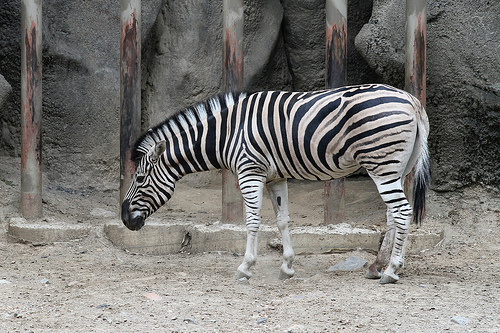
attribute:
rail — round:
[16, 0, 58, 227]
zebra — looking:
[119, 82, 430, 282]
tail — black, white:
[409, 96, 432, 230]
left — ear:
[151, 130, 171, 161]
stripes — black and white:
[119, 81, 434, 288]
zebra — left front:
[135, 95, 344, 225]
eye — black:
[134, 173, 146, 183]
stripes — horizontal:
[173, 119, 387, 154]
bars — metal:
[19, 0, 45, 222]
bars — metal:
[116, 2, 147, 213]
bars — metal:
[215, 0, 252, 223]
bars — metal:
[324, 0, 346, 229]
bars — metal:
[406, 0, 428, 101]